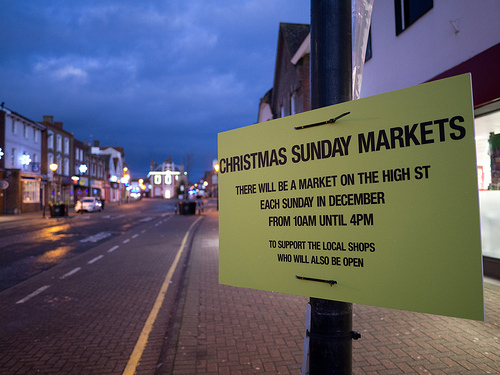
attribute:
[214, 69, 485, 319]
sign — advertisement, yellow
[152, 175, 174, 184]
rooms — lit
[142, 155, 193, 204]
building — small, lit up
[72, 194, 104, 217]
car — white, parked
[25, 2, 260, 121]
clouds — thin, white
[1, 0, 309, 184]
sky — blue, darkening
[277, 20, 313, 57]
roof — pointed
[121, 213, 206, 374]
line — yellow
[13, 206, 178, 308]
lines — white, broken up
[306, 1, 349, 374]
pole — black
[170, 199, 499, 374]
sidewalk — wide, brick, red brick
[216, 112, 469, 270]
letters — black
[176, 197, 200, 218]
trash can — garbage dumpster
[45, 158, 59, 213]
street lights — posted